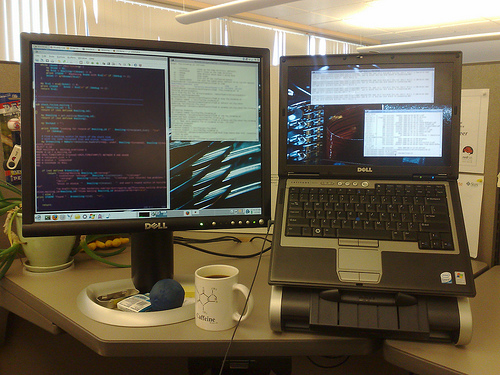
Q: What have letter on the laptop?
A: Keyboard.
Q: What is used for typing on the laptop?
A: Keyboard.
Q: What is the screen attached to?
A: Laptop.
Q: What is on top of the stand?
A: Laptop.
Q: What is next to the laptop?
A: Monitor.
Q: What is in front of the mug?
A: Monitor.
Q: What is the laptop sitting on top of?
A: Docking station.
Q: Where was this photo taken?
A: The office.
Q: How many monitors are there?
A: Two.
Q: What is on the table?
A: A coffee mug.